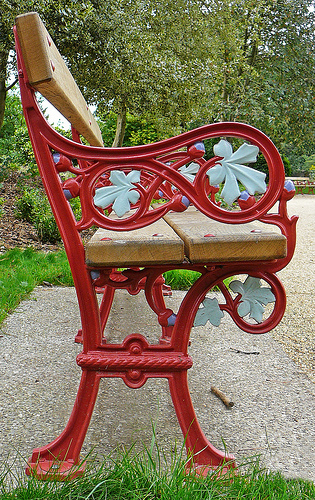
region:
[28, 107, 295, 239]
A red metal bench.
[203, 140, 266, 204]
White design on the bench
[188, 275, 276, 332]
White leaf design on the bench.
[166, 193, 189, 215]
Red flower with a white tip on the bench.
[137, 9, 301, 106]
Green trees in the park.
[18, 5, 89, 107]
The back of the bench is made of wood.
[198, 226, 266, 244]
Screws in the bench are painted red.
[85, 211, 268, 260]
The seat of the bench is made of wood.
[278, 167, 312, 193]
Another bench across the way.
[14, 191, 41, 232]
Small green bush behind the bench.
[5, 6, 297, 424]
red bench in park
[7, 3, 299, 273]
park bench with wooden back and seat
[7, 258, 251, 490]
ornate red metal legs of park bench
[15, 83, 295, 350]
ornate metal arms of park bench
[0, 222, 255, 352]
patch of grass around park bench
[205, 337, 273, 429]
twigs on ground at park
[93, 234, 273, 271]
red bolts in wooden park bench seat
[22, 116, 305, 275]
ornate floral arm rest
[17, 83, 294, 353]
park bench with ornate red metal work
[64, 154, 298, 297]
wooden seat of park bench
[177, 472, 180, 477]
edge of a lawn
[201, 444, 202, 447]
part of a chair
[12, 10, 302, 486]
an ornate red bench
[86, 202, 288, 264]
seat of the bench made from two wooden slats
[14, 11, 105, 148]
back of the bench made from one wooden board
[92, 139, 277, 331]
decorative leaves on the side of the bench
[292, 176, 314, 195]
another red bench in the background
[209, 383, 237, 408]
a stick on the ground in front of the bench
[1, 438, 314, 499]
tall grass next to the bench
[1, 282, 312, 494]
concrete slab under the bench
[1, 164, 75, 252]
mulch in the flower bed behind the bench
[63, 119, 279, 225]
red arm rest on chair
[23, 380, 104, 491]
red leg of chair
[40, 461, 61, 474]
silver bolt in chair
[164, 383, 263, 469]
red leg of chair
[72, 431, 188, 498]
green grass sticking up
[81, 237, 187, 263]
wooden bench on chair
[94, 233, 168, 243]
two red bolts on chair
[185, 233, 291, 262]
wooden bench on chair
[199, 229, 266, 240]
two red bolts on chair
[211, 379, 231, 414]
small stick on the ground